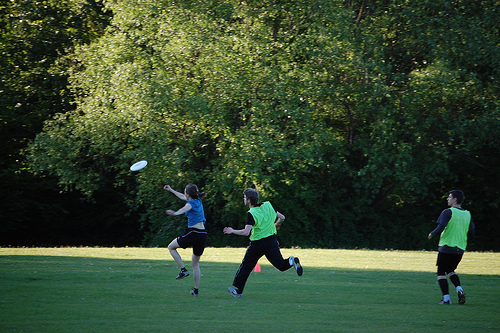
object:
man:
[163, 182, 212, 298]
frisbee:
[130, 160, 148, 171]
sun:
[0, 235, 500, 277]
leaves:
[178, 105, 185, 110]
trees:
[356, 57, 500, 250]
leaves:
[345, 99, 349, 103]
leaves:
[276, 108, 280, 111]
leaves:
[382, 129, 387, 134]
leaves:
[290, 63, 293, 66]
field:
[0, 243, 498, 331]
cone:
[253, 260, 260, 272]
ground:
[0, 229, 494, 331]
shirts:
[247, 200, 278, 242]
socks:
[438, 279, 450, 296]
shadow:
[0, 265, 499, 320]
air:
[0, 2, 494, 168]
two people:
[157, 181, 305, 300]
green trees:
[18, 0, 385, 245]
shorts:
[175, 227, 209, 257]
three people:
[157, 181, 473, 306]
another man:
[221, 187, 306, 300]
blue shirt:
[183, 197, 207, 228]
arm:
[168, 188, 187, 201]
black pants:
[231, 235, 294, 294]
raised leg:
[166, 236, 190, 268]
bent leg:
[262, 246, 289, 272]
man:
[222, 186, 303, 299]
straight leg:
[233, 240, 260, 290]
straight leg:
[190, 246, 205, 290]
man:
[426, 188, 474, 305]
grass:
[0, 242, 494, 333]